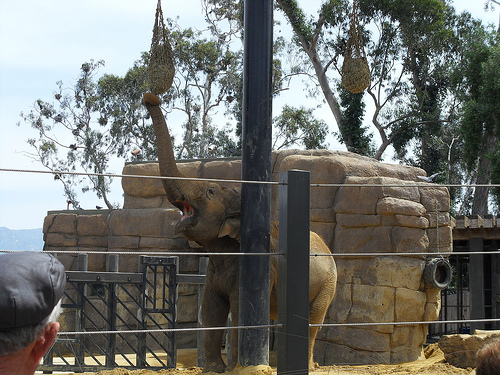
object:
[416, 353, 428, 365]
hay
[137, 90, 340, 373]
elephant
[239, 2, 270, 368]
pole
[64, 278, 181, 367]
bars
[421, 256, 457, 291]
tire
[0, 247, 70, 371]
man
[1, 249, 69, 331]
hat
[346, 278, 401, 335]
rock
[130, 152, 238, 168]
roofing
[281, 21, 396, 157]
tree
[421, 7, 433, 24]
foliage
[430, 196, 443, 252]
chain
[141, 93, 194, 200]
trunk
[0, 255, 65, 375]
head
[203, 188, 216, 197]
eye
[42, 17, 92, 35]
sky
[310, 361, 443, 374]
ground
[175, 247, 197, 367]
cage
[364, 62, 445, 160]
branches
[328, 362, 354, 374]
dirt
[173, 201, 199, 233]
mouth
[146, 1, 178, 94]
feeder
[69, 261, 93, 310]
gate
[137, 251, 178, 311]
rail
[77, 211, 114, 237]
boulders